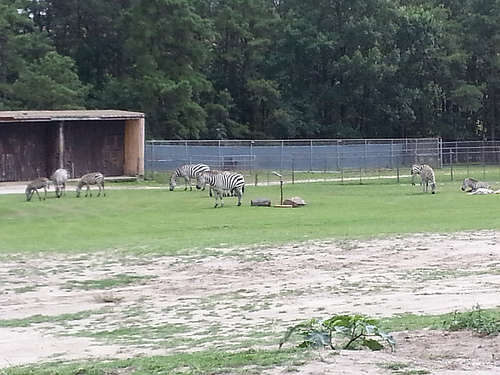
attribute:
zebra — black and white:
[408, 163, 438, 197]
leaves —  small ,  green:
[443, 303, 499, 338]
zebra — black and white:
[406, 157, 445, 195]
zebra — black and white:
[185, 155, 249, 217]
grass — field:
[8, 166, 492, 373]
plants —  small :
[275, 312, 398, 355]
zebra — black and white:
[72, 173, 104, 198]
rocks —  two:
[255, 187, 332, 229]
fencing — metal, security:
[144, 140, 497, 182]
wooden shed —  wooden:
[3, 99, 158, 193]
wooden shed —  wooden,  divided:
[2, 106, 147, 195]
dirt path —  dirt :
[10, 164, 415, 193]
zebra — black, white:
[51, 167, 71, 198]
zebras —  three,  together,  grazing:
[20, 162, 112, 202]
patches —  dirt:
[0, 220, 498, 372]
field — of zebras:
[4, 179, 497, 374]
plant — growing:
[278, 313, 394, 354]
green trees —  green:
[1, 2, 496, 134]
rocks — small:
[244, 195, 319, 208]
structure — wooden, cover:
[0, 107, 145, 182]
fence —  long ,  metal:
[141, 133, 496, 182]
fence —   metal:
[141, 140, 497, 190]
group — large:
[22, 150, 497, 208]